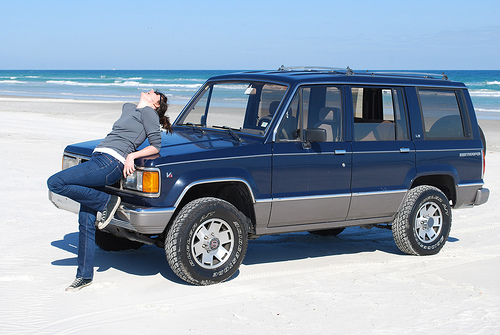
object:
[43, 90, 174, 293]
woman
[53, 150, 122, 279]
jeans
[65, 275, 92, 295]
shoe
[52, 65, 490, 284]
car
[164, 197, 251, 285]
wheel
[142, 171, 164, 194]
front light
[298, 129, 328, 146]
mirror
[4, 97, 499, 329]
beach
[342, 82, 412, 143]
window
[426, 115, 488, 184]
spare tire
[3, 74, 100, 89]
water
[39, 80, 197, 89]
foam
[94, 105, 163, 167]
hood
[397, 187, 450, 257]
wheel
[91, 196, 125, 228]
shoe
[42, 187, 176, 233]
bumper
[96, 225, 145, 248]
wheel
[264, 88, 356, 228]
door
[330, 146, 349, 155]
handle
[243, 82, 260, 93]
mirror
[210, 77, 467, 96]
ceiling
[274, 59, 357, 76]
roof rack